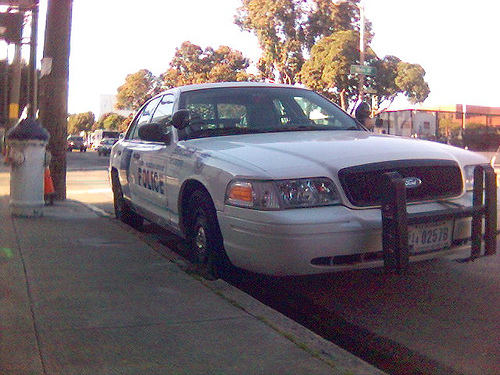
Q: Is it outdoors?
A: Yes, it is outdoors.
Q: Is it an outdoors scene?
A: Yes, it is outdoors.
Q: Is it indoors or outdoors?
A: It is outdoors.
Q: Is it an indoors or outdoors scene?
A: It is outdoors.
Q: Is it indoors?
A: No, it is outdoors.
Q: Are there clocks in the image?
A: No, there are no clocks.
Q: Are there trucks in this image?
A: No, there are no trucks.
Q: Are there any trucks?
A: No, there are no trucks.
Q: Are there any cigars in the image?
A: No, there are no cigars.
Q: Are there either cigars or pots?
A: No, there are no cigars or pots.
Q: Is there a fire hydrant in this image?
A: Yes, there is a fire hydrant.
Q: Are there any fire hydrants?
A: Yes, there is a fire hydrant.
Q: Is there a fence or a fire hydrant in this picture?
A: Yes, there is a fire hydrant.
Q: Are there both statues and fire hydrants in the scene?
A: No, there is a fire hydrant but no statues.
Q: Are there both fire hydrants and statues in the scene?
A: No, there is a fire hydrant but no statues.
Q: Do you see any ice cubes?
A: No, there are no ice cubes.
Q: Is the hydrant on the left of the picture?
A: Yes, the hydrant is on the left of the image.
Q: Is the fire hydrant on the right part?
A: No, the fire hydrant is on the left of the image.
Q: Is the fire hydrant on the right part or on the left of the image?
A: The fire hydrant is on the left of the image.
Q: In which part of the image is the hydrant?
A: The hydrant is on the left of the image.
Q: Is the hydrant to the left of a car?
A: Yes, the hydrant is to the left of a car.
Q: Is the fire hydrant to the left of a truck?
A: No, the fire hydrant is to the left of a car.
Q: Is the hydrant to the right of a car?
A: No, the hydrant is to the left of a car.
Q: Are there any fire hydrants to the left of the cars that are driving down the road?
A: Yes, there is a fire hydrant to the left of the cars.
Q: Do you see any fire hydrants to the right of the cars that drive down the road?
A: No, the fire hydrant is to the left of the cars.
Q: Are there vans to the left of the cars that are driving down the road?
A: No, there is a fire hydrant to the left of the cars.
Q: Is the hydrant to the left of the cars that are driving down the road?
A: Yes, the hydrant is to the left of the cars.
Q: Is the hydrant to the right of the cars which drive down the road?
A: No, the hydrant is to the left of the cars.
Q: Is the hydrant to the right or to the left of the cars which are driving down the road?
A: The hydrant is to the left of the cars.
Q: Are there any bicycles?
A: No, there are no bicycles.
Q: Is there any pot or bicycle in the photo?
A: No, there are no bicycles or pots.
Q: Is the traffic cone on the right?
A: No, the traffic cone is on the left of the image.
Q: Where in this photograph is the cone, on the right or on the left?
A: The cone is on the left of the image.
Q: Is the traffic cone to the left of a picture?
A: No, the traffic cone is to the left of a car.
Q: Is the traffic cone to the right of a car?
A: No, the traffic cone is to the left of a car.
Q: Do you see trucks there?
A: No, there are no trucks.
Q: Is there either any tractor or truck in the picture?
A: No, there are no trucks or tractors.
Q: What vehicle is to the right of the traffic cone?
A: The vehicle is a car.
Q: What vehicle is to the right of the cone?
A: The vehicle is a car.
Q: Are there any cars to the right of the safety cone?
A: Yes, there is a car to the right of the safety cone.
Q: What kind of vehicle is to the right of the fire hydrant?
A: The vehicle is a car.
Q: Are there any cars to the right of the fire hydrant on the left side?
A: Yes, there is a car to the right of the hydrant.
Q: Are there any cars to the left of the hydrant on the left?
A: No, the car is to the right of the fire hydrant.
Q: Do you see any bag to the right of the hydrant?
A: No, there is a car to the right of the hydrant.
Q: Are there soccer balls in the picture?
A: No, there are no soccer balls.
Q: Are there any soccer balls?
A: No, there are no soccer balls.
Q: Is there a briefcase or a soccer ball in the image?
A: No, there are no soccer balls or briefcases.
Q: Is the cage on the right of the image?
A: Yes, the cage is on the right of the image.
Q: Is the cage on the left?
A: No, the cage is on the right of the image.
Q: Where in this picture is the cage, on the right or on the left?
A: The cage is on the right of the image.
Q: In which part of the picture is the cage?
A: The cage is on the right of the image.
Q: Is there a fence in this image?
A: Yes, there is a fence.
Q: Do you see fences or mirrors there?
A: Yes, there is a fence.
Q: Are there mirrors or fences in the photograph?
A: Yes, there is a fence.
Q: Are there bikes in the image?
A: No, there are no bikes.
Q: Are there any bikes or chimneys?
A: No, there are no bikes or chimneys.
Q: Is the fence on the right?
A: Yes, the fence is on the right of the image.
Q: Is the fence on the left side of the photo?
A: No, the fence is on the right of the image.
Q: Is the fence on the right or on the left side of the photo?
A: The fence is on the right of the image.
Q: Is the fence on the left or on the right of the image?
A: The fence is on the right of the image.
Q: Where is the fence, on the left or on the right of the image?
A: The fence is on the right of the image.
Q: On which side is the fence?
A: The fence is on the right of the image.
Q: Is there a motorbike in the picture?
A: No, there are no motorcycles.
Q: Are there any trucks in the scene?
A: No, there are no trucks.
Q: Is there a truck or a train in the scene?
A: No, there are no trucks or trains.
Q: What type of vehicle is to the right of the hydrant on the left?
A: The vehicles are cars.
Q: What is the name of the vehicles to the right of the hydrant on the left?
A: The vehicles are cars.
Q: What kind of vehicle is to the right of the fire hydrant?
A: The vehicles are cars.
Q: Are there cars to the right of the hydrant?
A: Yes, there are cars to the right of the hydrant.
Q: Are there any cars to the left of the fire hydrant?
A: No, the cars are to the right of the fire hydrant.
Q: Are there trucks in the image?
A: No, there are no trucks.